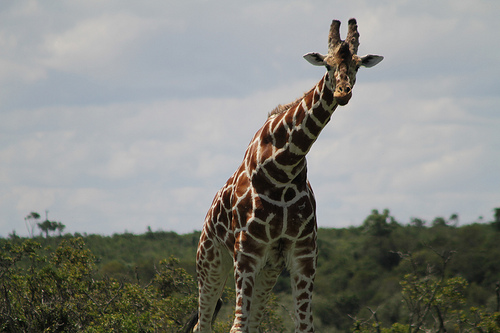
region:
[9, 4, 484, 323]
Large adult giraffe at a safari.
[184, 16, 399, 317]
Giraffe with large brown spots.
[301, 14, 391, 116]
Head of a giraffe.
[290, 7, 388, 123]
Horns of an adult giraffe.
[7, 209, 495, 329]
Grassland area of a safari.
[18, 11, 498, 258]
Cloudy sky during the day.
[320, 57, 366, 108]
Face of a giraffe.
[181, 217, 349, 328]
Legs of an adult giraffe.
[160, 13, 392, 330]
Giraffe with beige fur and dark brown spots.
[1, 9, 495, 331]
A large adult giraffe standing in a vast grassy area.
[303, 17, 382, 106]
head of the giraffe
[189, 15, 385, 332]
a brown and white colored giraffe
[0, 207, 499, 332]
area of grass and bushes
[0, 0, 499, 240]
cloudy grayish white sky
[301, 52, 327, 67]
right ear of the giraffe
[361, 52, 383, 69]
left ear of the giraffe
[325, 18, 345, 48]
right horn on the giraffe's head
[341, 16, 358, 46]
left horn on the giraffe's head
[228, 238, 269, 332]
right front leg of the giraffe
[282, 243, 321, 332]
left front leg of the giraffe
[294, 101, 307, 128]
brown spot on giraffe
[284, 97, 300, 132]
brown spot on giraffe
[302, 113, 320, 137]
brown spot on giraffe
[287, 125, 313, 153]
brown spot on giraffe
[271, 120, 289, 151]
brown spot on giraffe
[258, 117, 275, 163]
brown spot on giraffe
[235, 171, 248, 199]
brown spot on giraffe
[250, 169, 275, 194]
brown spot on giraffe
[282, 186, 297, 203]
brown spot on giraffe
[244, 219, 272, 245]
brown spot on giraffe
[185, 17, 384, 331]
Brown and white giraffe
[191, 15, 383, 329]
Giraffe posing for camera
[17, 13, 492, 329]
Giraffe out in wild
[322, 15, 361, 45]
Two horns on giraffe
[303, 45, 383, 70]
Ears sticking out on giraffe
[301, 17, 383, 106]
Head of giraffe facing camera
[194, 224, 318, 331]
Three legs on giraffe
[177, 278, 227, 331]
End of tail sticking out from giraffe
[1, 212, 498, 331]
Green, lush trees and vegetation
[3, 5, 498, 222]
Cloudy overcast skies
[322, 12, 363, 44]
ossicones on head of giraffe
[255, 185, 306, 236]
brown spots on giraffe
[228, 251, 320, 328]
two giraffe legs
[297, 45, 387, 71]
two giraffe ears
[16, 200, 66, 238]
trees in grass field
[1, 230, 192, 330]
bush next to giraffe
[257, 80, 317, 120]
brown giraffe mane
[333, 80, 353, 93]
two giraffe nostrils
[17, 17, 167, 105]
white cloud in sky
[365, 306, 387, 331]
tree branch